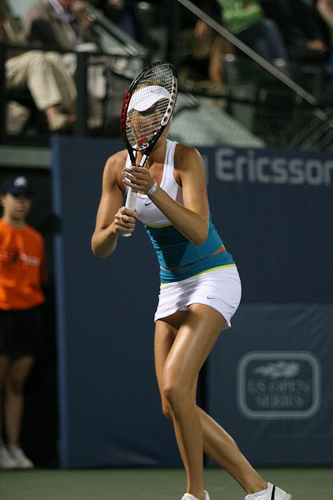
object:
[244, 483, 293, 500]
shoe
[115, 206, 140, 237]
fingers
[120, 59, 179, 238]
racket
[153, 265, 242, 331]
skirt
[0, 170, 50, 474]
girl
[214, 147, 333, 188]
ericsson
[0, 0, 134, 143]
crowd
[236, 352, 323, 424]
logo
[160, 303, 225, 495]
leg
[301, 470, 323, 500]
ground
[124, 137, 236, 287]
shirt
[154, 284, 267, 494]
leg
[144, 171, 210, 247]
arm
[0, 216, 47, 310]
shirt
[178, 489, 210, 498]
tennis shoe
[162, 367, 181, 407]
knees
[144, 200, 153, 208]
nike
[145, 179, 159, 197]
band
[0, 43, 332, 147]
railing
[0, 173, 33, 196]
dark cap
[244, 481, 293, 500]
foot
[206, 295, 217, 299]
logo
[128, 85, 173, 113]
visor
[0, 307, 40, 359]
dark shorts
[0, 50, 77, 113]
slacks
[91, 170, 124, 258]
arm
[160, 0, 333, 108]
people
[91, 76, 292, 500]
tennis